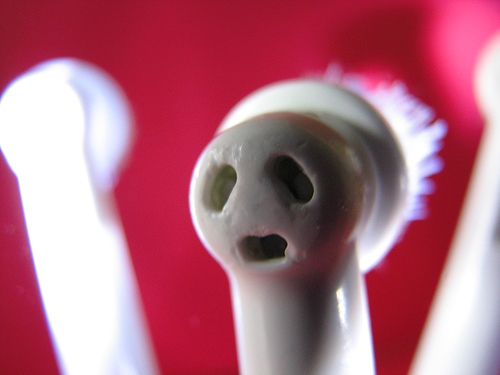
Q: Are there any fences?
A: No, there are no fences.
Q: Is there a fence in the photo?
A: No, there are no fences.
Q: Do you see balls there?
A: No, there are no balls.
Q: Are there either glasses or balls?
A: No, there are no balls or glasses.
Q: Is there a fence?
A: No, there are no fences.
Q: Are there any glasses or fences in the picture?
A: No, there are no fences or glasses.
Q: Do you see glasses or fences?
A: No, there are no fences or glasses.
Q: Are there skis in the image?
A: No, there are no skis.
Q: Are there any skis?
A: No, there are no skis.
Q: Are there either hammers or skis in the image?
A: No, there are no skis or hammers.